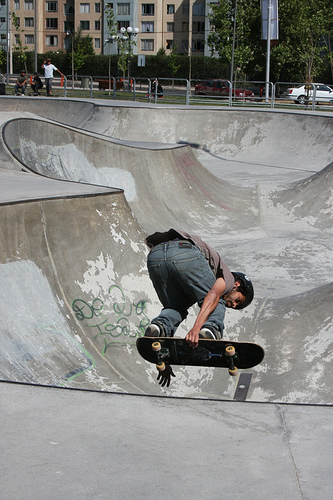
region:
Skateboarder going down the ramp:
[136, 215, 285, 395]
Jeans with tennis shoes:
[146, 243, 224, 340]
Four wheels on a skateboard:
[140, 338, 251, 377]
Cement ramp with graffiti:
[5, 191, 115, 385]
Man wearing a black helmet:
[230, 268, 259, 313]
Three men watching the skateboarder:
[14, 57, 61, 97]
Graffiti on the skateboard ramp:
[59, 271, 158, 349]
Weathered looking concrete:
[210, 120, 327, 329]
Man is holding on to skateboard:
[183, 252, 229, 359]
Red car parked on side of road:
[193, 68, 269, 127]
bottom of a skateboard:
[129, 329, 266, 371]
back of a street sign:
[252, 0, 276, 104]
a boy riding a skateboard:
[142, 219, 268, 408]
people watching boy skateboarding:
[13, 52, 74, 98]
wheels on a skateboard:
[217, 344, 242, 374]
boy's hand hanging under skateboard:
[152, 351, 177, 391]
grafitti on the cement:
[63, 277, 146, 353]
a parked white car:
[290, 82, 329, 103]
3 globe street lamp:
[114, 20, 143, 57]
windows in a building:
[138, 0, 157, 55]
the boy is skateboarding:
[135, 209, 271, 409]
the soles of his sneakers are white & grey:
[130, 319, 239, 341]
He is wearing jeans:
[127, 229, 223, 367]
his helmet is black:
[227, 250, 273, 317]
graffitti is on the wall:
[44, 272, 167, 358]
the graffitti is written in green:
[56, 284, 154, 360]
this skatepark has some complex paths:
[10, 95, 332, 397]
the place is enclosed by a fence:
[27, 67, 268, 114]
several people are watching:
[10, 48, 74, 105]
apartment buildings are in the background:
[24, 2, 200, 60]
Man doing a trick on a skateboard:
[135, 227, 264, 384]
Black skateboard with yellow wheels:
[135, 335, 265, 377]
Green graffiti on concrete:
[72, 283, 145, 347]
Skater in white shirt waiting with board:
[41, 59, 60, 98]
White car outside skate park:
[288, 80, 330, 108]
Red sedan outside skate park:
[191, 76, 254, 102]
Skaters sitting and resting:
[10, 70, 43, 97]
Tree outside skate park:
[279, 1, 328, 103]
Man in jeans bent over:
[144, 226, 253, 335]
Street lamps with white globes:
[110, 25, 139, 92]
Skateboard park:
[1, 95, 332, 499]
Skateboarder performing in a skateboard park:
[142, 227, 253, 349]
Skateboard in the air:
[132, 336, 264, 376]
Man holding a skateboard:
[40, 57, 66, 97]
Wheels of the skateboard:
[151, 341, 238, 376]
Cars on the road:
[194, 79, 332, 103]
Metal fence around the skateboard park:
[4, 73, 331, 107]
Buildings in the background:
[0, 2, 231, 52]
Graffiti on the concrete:
[34, 283, 150, 384]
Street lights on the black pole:
[120, 26, 139, 79]